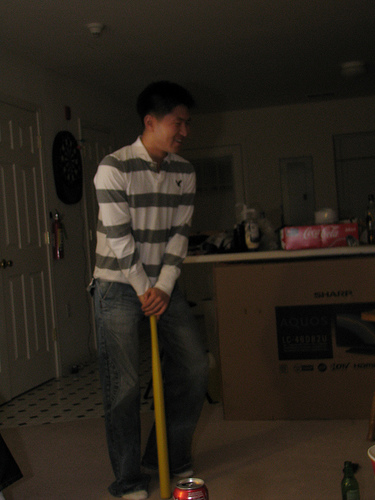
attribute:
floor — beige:
[5, 423, 373, 496]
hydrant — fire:
[50, 211, 67, 259]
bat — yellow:
[147, 291, 175, 498]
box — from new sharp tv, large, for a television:
[203, 261, 374, 416]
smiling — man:
[174, 138, 185, 146]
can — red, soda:
[141, 455, 239, 498]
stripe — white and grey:
[100, 152, 195, 173]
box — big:
[217, 259, 374, 411]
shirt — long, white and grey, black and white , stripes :
[86, 136, 198, 298]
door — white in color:
[0, 124, 38, 334]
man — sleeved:
[82, 83, 214, 489]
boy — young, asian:
[65, 67, 281, 302]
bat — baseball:
[119, 280, 190, 496]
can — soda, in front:
[175, 475, 209, 498]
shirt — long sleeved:
[91, 139, 205, 288]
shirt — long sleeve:
[96, 117, 204, 300]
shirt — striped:
[92, 134, 225, 332]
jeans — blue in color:
[72, 283, 234, 455]